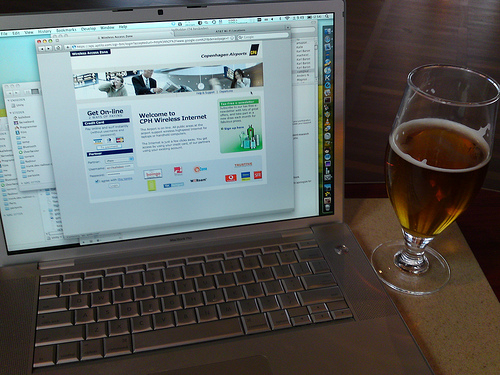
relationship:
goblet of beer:
[368, 64, 498, 298] [388, 117, 484, 231]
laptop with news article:
[0, 0, 435, 370] [132, 94, 218, 164]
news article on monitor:
[132, 94, 218, 164] [1, 14, 338, 250]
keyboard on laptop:
[11, 239, 353, 364] [0, 0, 435, 370]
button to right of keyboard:
[333, 244, 349, 258] [11, 239, 353, 364]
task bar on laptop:
[322, 25, 331, 208] [0, 0, 435, 370]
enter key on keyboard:
[304, 272, 329, 289] [11, 239, 353, 364]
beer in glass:
[388, 117, 484, 231] [366, 66, 496, 296]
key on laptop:
[280, 291, 299, 310] [0, 0, 435, 370]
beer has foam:
[388, 117, 484, 231] [388, 117, 495, 173]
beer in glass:
[385, 118, 490, 237] [366, 66, 496, 296]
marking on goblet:
[388, 158, 392, 167] [368, 64, 498, 298]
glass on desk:
[366, 66, 496, 296] [4, 203, 499, 371]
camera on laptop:
[157, 8, 163, 16] [0, 0, 435, 370]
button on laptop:
[333, 245, 343, 257] [0, 0, 435, 370]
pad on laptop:
[167, 353, 281, 373] [157, 350, 289, 371]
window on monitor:
[40, 23, 301, 236] [1, 14, 338, 250]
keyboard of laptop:
[11, 239, 353, 364] [0, 0, 435, 370]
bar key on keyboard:
[131, 317, 244, 352] [11, 239, 353, 364]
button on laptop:
[332, 241, 344, 257] [0, 0, 435, 370]